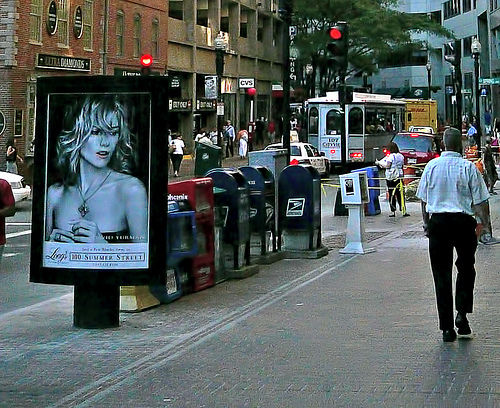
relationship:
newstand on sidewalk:
[330, 164, 391, 265] [189, 199, 500, 408]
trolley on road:
[303, 90, 407, 167] [3, 150, 500, 408]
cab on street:
[277, 130, 333, 187] [220, 162, 364, 209]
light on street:
[324, 17, 354, 81] [5, 202, 77, 315]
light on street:
[469, 32, 482, 64] [5, 202, 77, 315]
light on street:
[136, 50, 154, 69] [5, 202, 77, 315]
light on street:
[208, 29, 228, 68] [5, 202, 77, 315]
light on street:
[420, 59, 435, 86] [5, 202, 77, 315]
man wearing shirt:
[413, 126, 494, 343] [415, 148, 489, 218]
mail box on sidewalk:
[276, 162, 329, 260] [4, 200, 494, 396]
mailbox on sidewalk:
[239, 164, 283, 264] [4, 200, 494, 396]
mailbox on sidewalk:
[202, 165, 260, 279] [4, 200, 494, 396]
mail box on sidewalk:
[276, 162, 329, 260] [138, 237, 428, 359]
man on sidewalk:
[413, 126, 494, 343] [215, 219, 435, 371]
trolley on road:
[300, 88, 406, 168] [3, 162, 378, 327]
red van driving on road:
[383, 132, 443, 172] [318, 172, 339, 218]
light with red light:
[326, 23, 346, 74] [328, 27, 341, 40]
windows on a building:
[110, 2, 160, 60] [46, 24, 428, 308]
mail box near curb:
[280, 162, 325, 261] [0, 286, 66, 308]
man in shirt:
[414, 123, 496, 344] [415, 148, 489, 218]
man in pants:
[414, 123, 496, 344] [427, 212, 480, 329]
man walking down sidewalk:
[414, 123, 496, 344] [4, 200, 494, 396]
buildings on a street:
[0, 0, 172, 74] [1, 274, 44, 302]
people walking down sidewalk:
[189, 118, 271, 148] [331, 223, 476, 400]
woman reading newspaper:
[380, 141, 412, 219] [373, 153, 392, 167]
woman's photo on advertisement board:
[47, 97, 147, 246] [24, 69, 175, 333]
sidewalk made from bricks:
[0, 332, 477, 401] [230, 372, 264, 391]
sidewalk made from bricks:
[0, 332, 477, 401] [351, 372, 380, 389]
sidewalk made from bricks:
[0, 332, 477, 401] [273, 321, 290, 343]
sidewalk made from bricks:
[0, 332, 477, 401] [146, 343, 178, 367]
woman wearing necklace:
[22, 67, 179, 287] [71, 168, 114, 214]